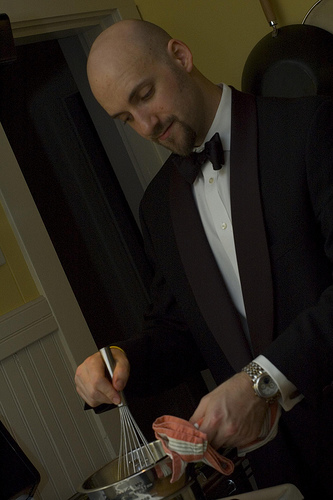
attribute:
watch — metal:
[243, 359, 283, 406]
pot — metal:
[82, 437, 187, 499]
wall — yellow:
[140, 0, 332, 100]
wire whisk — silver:
[87, 333, 179, 497]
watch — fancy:
[240, 363, 284, 401]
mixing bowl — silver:
[52, 426, 206, 498]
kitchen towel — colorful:
[145, 398, 245, 488]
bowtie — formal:
[161, 135, 247, 185]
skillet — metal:
[225, 2, 329, 103]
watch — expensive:
[230, 349, 306, 410]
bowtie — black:
[173, 136, 251, 183]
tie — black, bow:
[151, 136, 249, 186]